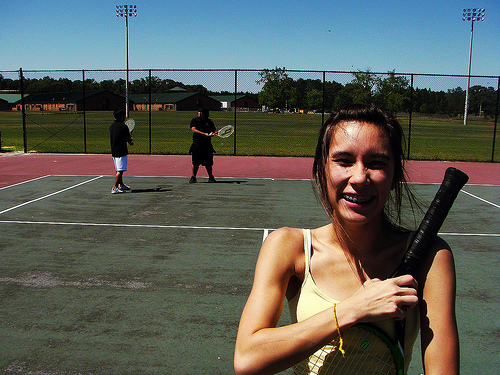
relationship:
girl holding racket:
[233, 103, 461, 374] [276, 166, 469, 374]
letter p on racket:
[359, 337, 371, 350] [276, 166, 469, 374]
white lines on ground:
[0, 174, 497, 236] [4, 153, 499, 373]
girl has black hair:
[233, 103, 461, 374] [311, 103, 424, 225]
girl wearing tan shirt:
[233, 103, 461, 374] [288, 228, 423, 374]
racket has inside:
[276, 166, 469, 374] [293, 326, 397, 374]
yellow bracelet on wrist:
[332, 301, 348, 356] [328, 300, 367, 330]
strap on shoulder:
[303, 227, 312, 275] [266, 228, 334, 277]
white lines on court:
[0, 174, 497, 236] [1, 174, 498, 374]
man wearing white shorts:
[107, 109, 135, 193] [111, 155, 126, 171]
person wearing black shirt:
[107, 109, 135, 193] [109, 120, 131, 155]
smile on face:
[333, 178, 383, 216] [323, 120, 395, 222]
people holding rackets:
[107, 106, 221, 191] [119, 117, 235, 140]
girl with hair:
[233, 103, 461, 374] [311, 103, 424, 225]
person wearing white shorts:
[107, 109, 135, 193] [111, 155, 126, 171]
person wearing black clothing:
[188, 106, 218, 181] [190, 118, 216, 168]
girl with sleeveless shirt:
[233, 103, 461, 374] [288, 228, 423, 374]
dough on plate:
[3, 146, 18, 152] [1, 145, 16, 154]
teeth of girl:
[340, 192, 378, 204] [233, 103, 461, 374]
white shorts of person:
[111, 155, 126, 171] [107, 109, 135, 193]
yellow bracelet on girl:
[332, 301, 348, 356] [233, 103, 461, 374]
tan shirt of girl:
[288, 228, 423, 374] [233, 103, 461, 374]